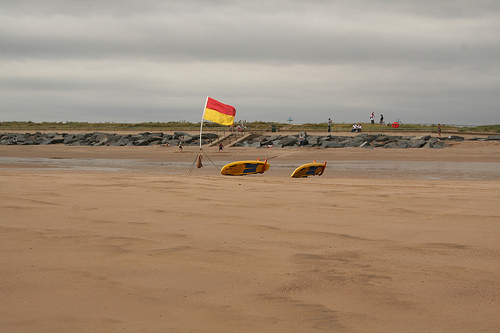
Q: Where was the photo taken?
A: The beach.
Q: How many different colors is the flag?
A: 2.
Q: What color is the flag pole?
A: White.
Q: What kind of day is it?
A: Overcast.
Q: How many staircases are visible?
A: 1.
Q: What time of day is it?
A: Daytime.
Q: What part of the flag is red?
A: Top.